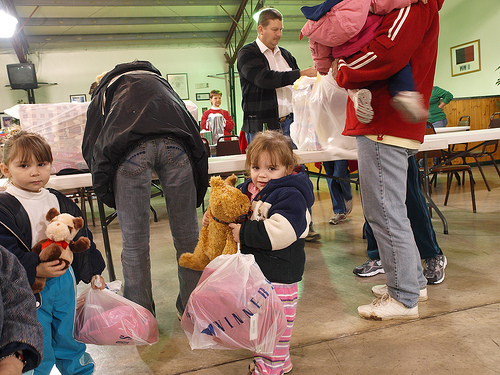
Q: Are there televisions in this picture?
A: Yes, there is a television.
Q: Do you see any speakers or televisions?
A: Yes, there is a television.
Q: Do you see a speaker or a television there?
A: Yes, there is a television.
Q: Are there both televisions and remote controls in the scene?
A: No, there is a television but no remote controls.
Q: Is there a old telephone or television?
A: Yes, there is an old television.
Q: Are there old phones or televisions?
A: Yes, there is an old television.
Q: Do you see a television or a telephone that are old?
A: Yes, the television is old.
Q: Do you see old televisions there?
A: Yes, there is an old television.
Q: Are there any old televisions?
A: Yes, there is an old television.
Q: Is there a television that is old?
A: Yes, there is a television that is old.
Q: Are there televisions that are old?
A: Yes, there is a television that is old.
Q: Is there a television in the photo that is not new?
A: Yes, there is a old television.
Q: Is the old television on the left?
A: Yes, the TV is on the left of the image.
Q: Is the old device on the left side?
A: Yes, the TV is on the left of the image.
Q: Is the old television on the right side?
A: No, the television is on the left of the image.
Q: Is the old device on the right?
A: No, the television is on the left of the image.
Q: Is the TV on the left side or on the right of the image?
A: The TV is on the left of the image.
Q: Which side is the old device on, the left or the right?
A: The TV is on the left of the image.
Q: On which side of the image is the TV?
A: The TV is on the left of the image.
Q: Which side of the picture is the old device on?
A: The TV is on the left of the image.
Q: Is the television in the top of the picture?
A: Yes, the television is in the top of the image.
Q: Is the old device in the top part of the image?
A: Yes, the television is in the top of the image.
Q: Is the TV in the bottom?
A: No, the TV is in the top of the image.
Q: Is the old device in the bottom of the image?
A: No, the TV is in the top of the image.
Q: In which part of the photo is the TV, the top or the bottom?
A: The TV is in the top of the image.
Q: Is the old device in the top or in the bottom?
A: The TV is in the top of the image.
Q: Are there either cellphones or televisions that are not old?
A: No, there is a television but it is old.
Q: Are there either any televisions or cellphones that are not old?
A: No, there is a television but it is old.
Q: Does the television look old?
A: Yes, the television is old.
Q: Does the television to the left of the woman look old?
A: Yes, the television is old.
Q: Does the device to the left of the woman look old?
A: Yes, the television is old.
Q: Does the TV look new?
A: No, the TV is old.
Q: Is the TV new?
A: No, the TV is old.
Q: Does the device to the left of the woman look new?
A: No, the TV is old.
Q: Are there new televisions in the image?
A: No, there is a television but it is old.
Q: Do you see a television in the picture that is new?
A: No, there is a television but it is old.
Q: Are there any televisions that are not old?
A: No, there is a television but it is old.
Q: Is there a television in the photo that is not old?
A: No, there is a television but it is old.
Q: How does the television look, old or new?
A: The television is old.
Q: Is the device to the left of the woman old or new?
A: The television is old.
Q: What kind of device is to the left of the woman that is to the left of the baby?
A: The device is a television.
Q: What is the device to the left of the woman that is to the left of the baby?
A: The device is a television.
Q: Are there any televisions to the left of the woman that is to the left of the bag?
A: Yes, there is a television to the left of the woman.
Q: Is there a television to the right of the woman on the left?
A: No, the television is to the left of the woman.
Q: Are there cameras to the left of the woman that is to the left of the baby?
A: No, there is a television to the left of the woman.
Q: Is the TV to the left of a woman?
A: Yes, the TV is to the left of a woman.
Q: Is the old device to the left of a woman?
A: Yes, the TV is to the left of a woman.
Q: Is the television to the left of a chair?
A: No, the television is to the left of a woman.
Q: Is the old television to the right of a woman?
A: No, the TV is to the left of a woman.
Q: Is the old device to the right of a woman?
A: No, the TV is to the left of a woman.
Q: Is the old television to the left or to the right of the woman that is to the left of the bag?
A: The TV is to the left of the woman.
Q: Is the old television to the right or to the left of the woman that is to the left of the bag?
A: The TV is to the left of the woman.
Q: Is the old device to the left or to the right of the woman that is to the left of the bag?
A: The TV is to the left of the woman.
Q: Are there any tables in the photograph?
A: Yes, there is a table.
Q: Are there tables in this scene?
A: Yes, there is a table.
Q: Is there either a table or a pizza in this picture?
A: Yes, there is a table.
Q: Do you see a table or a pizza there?
A: Yes, there is a table.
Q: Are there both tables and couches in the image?
A: No, there is a table but no couches.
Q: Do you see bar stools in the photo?
A: No, there are no bar stools.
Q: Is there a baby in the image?
A: Yes, there is a baby.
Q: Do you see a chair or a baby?
A: Yes, there is a baby.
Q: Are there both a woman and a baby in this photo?
A: Yes, there are both a baby and a woman.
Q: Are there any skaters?
A: No, there are no skaters.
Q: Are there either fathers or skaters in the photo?
A: No, there are no skaters or fathers.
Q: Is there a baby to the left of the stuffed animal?
A: Yes, there is a baby to the left of the stuffed animal.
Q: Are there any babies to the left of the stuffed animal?
A: Yes, there is a baby to the left of the stuffed animal.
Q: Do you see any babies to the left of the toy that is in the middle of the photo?
A: Yes, there is a baby to the left of the stuffed animal.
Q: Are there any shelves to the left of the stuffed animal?
A: No, there is a baby to the left of the stuffed animal.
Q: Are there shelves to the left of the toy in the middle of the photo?
A: No, there is a baby to the left of the stuffed animal.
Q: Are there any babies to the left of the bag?
A: Yes, there is a baby to the left of the bag.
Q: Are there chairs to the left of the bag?
A: No, there is a baby to the left of the bag.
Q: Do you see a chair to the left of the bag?
A: No, there is a baby to the left of the bag.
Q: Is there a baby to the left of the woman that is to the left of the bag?
A: Yes, there is a baby to the left of the woman.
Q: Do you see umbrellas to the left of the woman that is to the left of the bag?
A: No, there is a baby to the left of the woman.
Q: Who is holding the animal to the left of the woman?
A: The baby is holding the animal.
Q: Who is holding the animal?
A: The baby is holding the animal.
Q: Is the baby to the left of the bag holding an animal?
A: Yes, the baby is holding an animal.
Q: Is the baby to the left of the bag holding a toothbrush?
A: No, the baby is holding an animal.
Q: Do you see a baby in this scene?
A: Yes, there is a baby.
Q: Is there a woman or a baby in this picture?
A: Yes, there is a baby.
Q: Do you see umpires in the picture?
A: No, there are no umpires.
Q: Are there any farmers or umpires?
A: No, there are no umpires or farmers.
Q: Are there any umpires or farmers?
A: No, there are no umpires or farmers.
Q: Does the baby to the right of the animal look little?
A: Yes, the baby is little.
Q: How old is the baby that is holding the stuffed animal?
A: The baby is little.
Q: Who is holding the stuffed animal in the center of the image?
A: The baby is holding the stuffed animal.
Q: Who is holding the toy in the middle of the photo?
A: The baby is holding the stuffed animal.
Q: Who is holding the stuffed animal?
A: The baby is holding the stuffed animal.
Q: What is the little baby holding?
A: The baby is holding the stuffed animal.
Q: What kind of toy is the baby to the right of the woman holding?
A: The baby is holding the stuffed animal.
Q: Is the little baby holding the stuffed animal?
A: Yes, the baby is holding the stuffed animal.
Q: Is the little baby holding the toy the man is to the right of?
A: Yes, the baby is holding the stuffed animal.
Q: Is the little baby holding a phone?
A: No, the baby is holding the stuffed animal.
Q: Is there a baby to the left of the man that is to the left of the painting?
A: Yes, there is a baby to the left of the man.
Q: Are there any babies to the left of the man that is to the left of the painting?
A: Yes, there is a baby to the left of the man.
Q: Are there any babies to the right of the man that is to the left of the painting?
A: No, the baby is to the left of the man.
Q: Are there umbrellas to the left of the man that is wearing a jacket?
A: No, there is a baby to the left of the man.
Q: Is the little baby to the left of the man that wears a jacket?
A: Yes, the baby is to the left of the man.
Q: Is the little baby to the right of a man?
A: No, the baby is to the left of a man.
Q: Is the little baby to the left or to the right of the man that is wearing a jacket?
A: The baby is to the left of the man.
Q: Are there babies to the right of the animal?
A: Yes, there is a baby to the right of the animal.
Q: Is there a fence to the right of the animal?
A: No, there is a baby to the right of the animal.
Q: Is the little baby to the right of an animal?
A: Yes, the baby is to the right of an animal.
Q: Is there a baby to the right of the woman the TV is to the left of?
A: Yes, there is a baby to the right of the woman.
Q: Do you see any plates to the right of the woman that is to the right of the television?
A: No, there is a baby to the right of the woman.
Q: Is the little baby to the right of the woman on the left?
A: Yes, the baby is to the right of the woman.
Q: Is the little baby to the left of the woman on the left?
A: No, the baby is to the right of the woman.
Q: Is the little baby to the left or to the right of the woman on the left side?
A: The baby is to the right of the woman.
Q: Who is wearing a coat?
A: The baby is wearing a coat.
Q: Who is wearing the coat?
A: The baby is wearing a coat.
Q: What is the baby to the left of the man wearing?
A: The baby is wearing a coat.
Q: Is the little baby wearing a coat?
A: Yes, the baby is wearing a coat.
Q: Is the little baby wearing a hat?
A: No, the baby is wearing a coat.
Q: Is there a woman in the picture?
A: Yes, there is a woman.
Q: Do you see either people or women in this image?
A: Yes, there is a woman.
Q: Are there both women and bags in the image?
A: Yes, there are both a woman and a bag.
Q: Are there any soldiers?
A: No, there are no soldiers.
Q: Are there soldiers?
A: No, there are no soldiers.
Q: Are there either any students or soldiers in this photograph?
A: No, there are no soldiers or students.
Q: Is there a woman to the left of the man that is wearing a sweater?
A: Yes, there is a woman to the left of the man.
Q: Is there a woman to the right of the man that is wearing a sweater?
A: No, the woman is to the left of the man.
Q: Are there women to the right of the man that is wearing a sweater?
A: No, the woman is to the left of the man.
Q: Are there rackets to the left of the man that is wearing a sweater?
A: No, there is a woman to the left of the man.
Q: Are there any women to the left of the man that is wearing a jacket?
A: Yes, there is a woman to the left of the man.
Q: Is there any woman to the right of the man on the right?
A: No, the woman is to the left of the man.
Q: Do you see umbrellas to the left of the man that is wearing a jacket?
A: No, there is a woman to the left of the man.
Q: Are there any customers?
A: No, there are no customers.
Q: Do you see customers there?
A: No, there are no customers.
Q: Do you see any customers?
A: No, there are no customers.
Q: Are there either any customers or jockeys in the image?
A: No, there are no customers or jockeys.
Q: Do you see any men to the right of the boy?
A: Yes, there is a man to the right of the boy.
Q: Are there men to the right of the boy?
A: Yes, there is a man to the right of the boy.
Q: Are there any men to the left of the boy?
A: No, the man is to the right of the boy.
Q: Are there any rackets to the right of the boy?
A: No, there is a man to the right of the boy.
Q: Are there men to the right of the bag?
A: Yes, there is a man to the right of the bag.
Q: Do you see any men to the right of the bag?
A: Yes, there is a man to the right of the bag.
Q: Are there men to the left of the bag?
A: No, the man is to the right of the bag.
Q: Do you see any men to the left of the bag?
A: No, the man is to the right of the bag.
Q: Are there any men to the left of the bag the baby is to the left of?
A: No, the man is to the right of the bag.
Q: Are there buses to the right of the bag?
A: No, there is a man to the right of the bag.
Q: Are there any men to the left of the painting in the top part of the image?
A: Yes, there is a man to the left of the painting.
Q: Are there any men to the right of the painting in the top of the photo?
A: No, the man is to the left of the painting.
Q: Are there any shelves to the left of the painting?
A: No, there is a man to the left of the painting.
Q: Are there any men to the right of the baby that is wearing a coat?
A: Yes, there is a man to the right of the baby.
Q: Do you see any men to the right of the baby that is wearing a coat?
A: Yes, there is a man to the right of the baby.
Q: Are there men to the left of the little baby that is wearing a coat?
A: No, the man is to the right of the baby.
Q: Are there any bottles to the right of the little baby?
A: No, there is a man to the right of the baby.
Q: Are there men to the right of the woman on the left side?
A: Yes, there is a man to the right of the woman.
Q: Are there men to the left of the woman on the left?
A: No, the man is to the right of the woman.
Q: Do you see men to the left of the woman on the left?
A: No, the man is to the right of the woman.